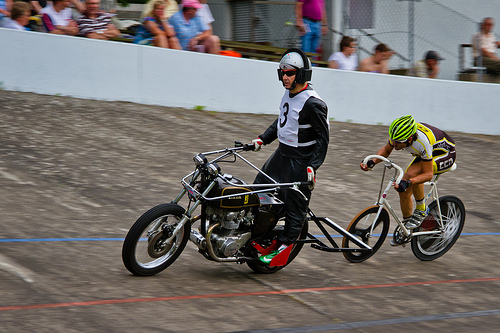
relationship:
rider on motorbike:
[279, 54, 322, 170] [124, 140, 370, 280]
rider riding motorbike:
[279, 54, 322, 170] [124, 140, 370, 280]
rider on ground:
[279, 54, 322, 170] [54, 147, 105, 189]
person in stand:
[158, 2, 170, 21] [143, 50, 209, 89]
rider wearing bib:
[279, 54, 322, 170] [278, 99, 305, 130]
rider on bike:
[389, 117, 454, 196] [384, 183, 389, 200]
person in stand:
[182, 2, 215, 22] [143, 50, 209, 89]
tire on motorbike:
[357, 209, 388, 251] [124, 140, 370, 280]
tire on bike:
[440, 204, 461, 245] [384, 183, 389, 200]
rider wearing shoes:
[389, 117, 454, 196] [410, 206, 427, 234]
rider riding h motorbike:
[279, 54, 322, 170] [124, 140, 370, 280]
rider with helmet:
[279, 54, 322, 170] [284, 56, 295, 66]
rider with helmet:
[389, 117, 454, 196] [399, 120, 410, 140]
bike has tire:
[384, 183, 389, 200] [357, 209, 388, 251]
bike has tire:
[384, 183, 389, 200] [440, 204, 461, 245]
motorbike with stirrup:
[124, 140, 370, 280] [279, 257, 284, 263]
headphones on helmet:
[305, 71, 313, 78] [284, 56, 295, 66]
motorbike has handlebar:
[124, 140, 370, 280] [259, 185, 293, 186]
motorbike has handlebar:
[214, 148, 238, 154] [225, 150, 237, 151]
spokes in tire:
[432, 221, 447, 247] [357, 209, 388, 251]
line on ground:
[37, 235, 80, 245] [54, 147, 105, 189]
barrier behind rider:
[387, 84, 443, 113] [279, 54, 322, 170]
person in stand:
[340, 38, 357, 57] [143, 50, 209, 89]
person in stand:
[88, 0, 102, 12] [143, 50, 209, 89]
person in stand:
[16, 3, 35, 22] [143, 50, 209, 89]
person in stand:
[305, 7, 324, 20] [143, 50, 209, 89]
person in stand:
[481, 20, 489, 43] [143, 50, 209, 89]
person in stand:
[377, 45, 390, 59] [143, 50, 209, 89]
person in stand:
[411, 45, 443, 70] [143, 50, 209, 89]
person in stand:
[55, 4, 67, 19] [143, 50, 209, 89]